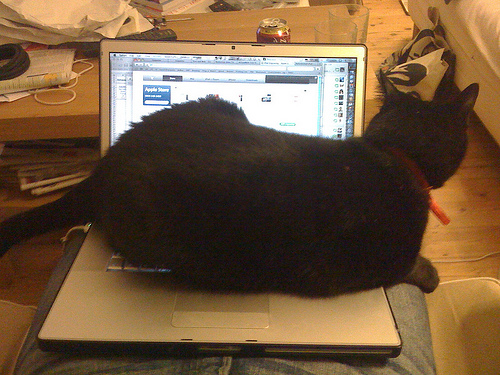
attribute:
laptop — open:
[44, 49, 419, 349]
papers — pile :
[13, 145, 102, 192]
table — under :
[8, 4, 373, 152]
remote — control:
[393, 0, 414, 20]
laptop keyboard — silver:
[32, 254, 341, 367]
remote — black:
[54, 26, 175, 57]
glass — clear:
[312, 0, 377, 49]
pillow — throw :
[373, 36, 464, 102]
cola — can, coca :
[251, 15, 293, 40]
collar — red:
[383, 142, 450, 232]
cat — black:
[0, 67, 479, 294]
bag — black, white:
[381, 18, 454, 102]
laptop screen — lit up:
[107, 43, 364, 159]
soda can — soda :
[258, 17, 290, 47]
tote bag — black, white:
[373, 22, 458, 109]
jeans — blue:
[13, 229, 433, 371]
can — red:
[254, 7, 292, 42]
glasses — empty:
[286, 0, 396, 48]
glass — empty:
[311, 5, 375, 37]